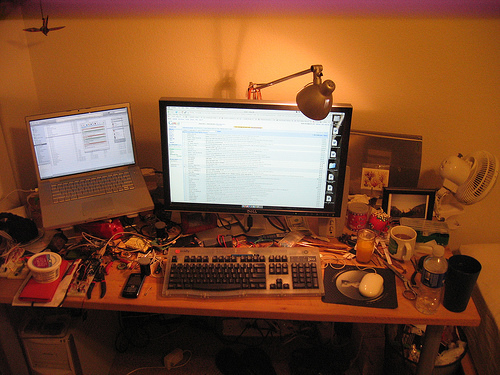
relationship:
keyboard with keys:
[156, 240, 333, 303] [236, 245, 255, 295]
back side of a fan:
[452, 180, 489, 282] [438, 155, 468, 193]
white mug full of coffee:
[387, 219, 418, 264] [392, 227, 414, 238]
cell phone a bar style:
[120, 270, 144, 299] [98, 239, 148, 369]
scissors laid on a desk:
[383, 260, 423, 302] [0, 192, 481, 374]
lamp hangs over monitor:
[245, 55, 337, 122] [167, 105, 330, 212]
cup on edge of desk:
[437, 239, 485, 347] [0, 154, 485, 366]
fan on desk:
[434, 149, 499, 229] [1, 204, 481, 329]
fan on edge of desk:
[405, 145, 499, 226] [392, 166, 460, 366]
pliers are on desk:
[94, 266, 111, 308] [40, 225, 134, 375]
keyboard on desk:
[161, 247, 326, 300] [6, 157, 490, 336]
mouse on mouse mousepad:
[353, 267, 390, 303] [320, 263, 398, 310]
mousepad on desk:
[319, 260, 399, 307] [3, 177, 482, 328]